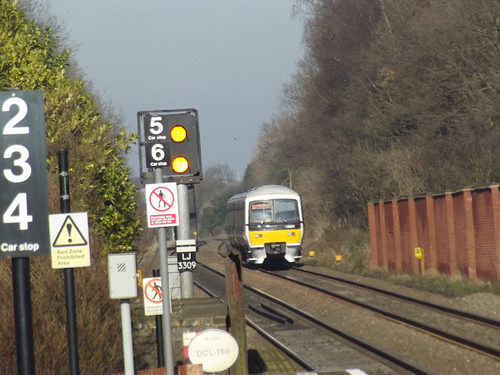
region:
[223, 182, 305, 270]
a white and yellow train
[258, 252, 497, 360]
a set of railroad tracks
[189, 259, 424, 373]
a set of railroad tracks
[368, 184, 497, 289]
a red brick wall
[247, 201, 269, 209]
electronic train destination sign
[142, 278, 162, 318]
a no walking sign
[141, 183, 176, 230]
a no walking sign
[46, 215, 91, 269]
a yellow caution sign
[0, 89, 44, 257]
a informational traffic sign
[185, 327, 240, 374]
a set of railroad tracks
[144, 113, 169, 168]
Track number fifty six.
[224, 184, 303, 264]
A yellow and white train.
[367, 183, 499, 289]
A fence made out of red bricks.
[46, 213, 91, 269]
A warning sign.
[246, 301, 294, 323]
Train tracks that change direction.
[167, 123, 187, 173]
Two yellow caution lights.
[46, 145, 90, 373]
A warning sign on a black pole.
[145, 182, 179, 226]
A no running across the tracks sign.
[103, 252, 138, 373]
A silver electrical box.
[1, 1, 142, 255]
A leafy green tree.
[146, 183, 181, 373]
no pedestrian crossing sign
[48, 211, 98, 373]
white and black red zone sign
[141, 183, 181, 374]
two no pedestrian crossing signs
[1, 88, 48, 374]
black and white sign with 2 3 4 printed on it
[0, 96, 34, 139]
the number 2 on a black sign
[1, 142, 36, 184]
the number 3 on a black sign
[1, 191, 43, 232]
the number 4 printed on a black sign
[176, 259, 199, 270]
the number 3309 printed on a black sign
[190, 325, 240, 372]
circular white sign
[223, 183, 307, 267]
white and yellow train on a track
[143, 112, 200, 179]
Yellow caution railroad lights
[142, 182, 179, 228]
No walking railroad sign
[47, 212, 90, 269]
Exclamation point sign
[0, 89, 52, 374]
Black sign with white numbers on a black pole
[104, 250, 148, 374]
Gray enclosed railroad electric box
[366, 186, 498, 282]
Tall red brick wall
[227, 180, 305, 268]
Silver and yellow moving train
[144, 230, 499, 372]
Two railroad tracks with one train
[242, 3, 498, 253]
Wooded area with little foilage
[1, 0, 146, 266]
Large green bush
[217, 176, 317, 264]
white and yellow train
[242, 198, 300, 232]
windshield on a train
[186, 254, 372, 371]
empty metal railroad track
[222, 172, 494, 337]
train on railroad track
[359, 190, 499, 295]
brown wooden fence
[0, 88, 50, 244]
black sign with numbers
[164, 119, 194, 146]
yellow light on a post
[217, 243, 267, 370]
old dirty wooden post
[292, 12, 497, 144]
trees with no leaves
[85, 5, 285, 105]
grey dark cloudless sky